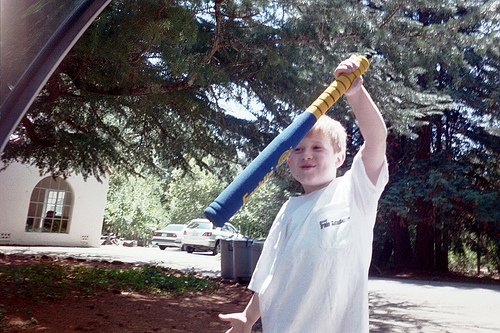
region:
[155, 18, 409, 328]
boy holding a bat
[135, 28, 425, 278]
the bat is blue and yellow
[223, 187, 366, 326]
boy's shirt is white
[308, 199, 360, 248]
black letters on shirt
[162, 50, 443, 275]
boy holding bat towards ground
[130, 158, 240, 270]
cars parked beside building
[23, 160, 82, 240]
the window is arched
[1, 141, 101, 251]
the building is white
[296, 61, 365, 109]
red lines on bat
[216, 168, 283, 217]
yellow lettering on bat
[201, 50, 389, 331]
little boy holding a bat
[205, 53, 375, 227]
bat is blue and yellow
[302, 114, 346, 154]
boy has blond hair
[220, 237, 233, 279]
farthest trash can is gray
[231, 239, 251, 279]
middle trash can is gray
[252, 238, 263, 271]
closest trash can is gray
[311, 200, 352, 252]
shirt pocket has printing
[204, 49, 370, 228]
left hand holding bat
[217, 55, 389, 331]
little boy is smiling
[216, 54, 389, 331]
little boy wearing white shirt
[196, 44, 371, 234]
boy is holding a blue bat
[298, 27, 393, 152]
blue bat has a yellow and red striped handle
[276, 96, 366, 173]
the little boy has blonde hair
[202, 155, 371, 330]
the little boy is wearing a white shirt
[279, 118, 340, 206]
the little boy looks happy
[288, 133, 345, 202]
the little boy is smiling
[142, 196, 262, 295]
a car and a van parked in the background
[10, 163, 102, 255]
an arched window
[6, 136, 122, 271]
part of a building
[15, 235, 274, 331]
dirt and shrubbery on the ground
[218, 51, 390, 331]
a young boy holding a Nerf bat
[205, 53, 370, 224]
a Nerf bat in the boy's hand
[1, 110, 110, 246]
a white building behind the boy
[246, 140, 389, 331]
a white t-shirt on the boy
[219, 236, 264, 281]
garbage cans on the boy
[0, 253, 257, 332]
a dirt-covered area behind the boy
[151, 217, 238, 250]
cars parked behind the boy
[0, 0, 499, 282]
trees behind the boy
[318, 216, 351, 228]
black writing on the boy's shirt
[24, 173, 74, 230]
arched window on the building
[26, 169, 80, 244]
window with an arch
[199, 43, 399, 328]
boy with bat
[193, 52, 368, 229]
blue and yellow foam bat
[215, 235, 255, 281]
two grey trash cans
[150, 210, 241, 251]
two parked cars in the driveway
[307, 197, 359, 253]
white shirt pocket with black writing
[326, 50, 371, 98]
hand holding bat handle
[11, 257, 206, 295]
weeds in the dirt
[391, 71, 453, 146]
pine tree branch hanging down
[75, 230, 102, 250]
vent on white house